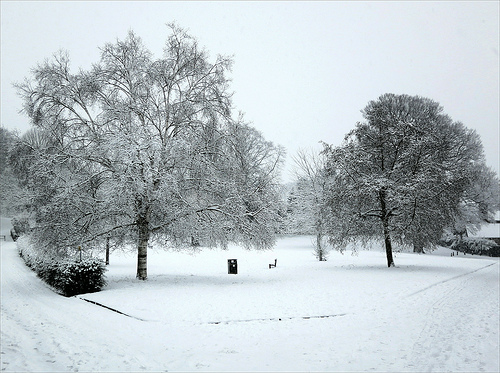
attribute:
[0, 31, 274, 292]
tree — snow-covered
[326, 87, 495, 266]
tree — snow-covered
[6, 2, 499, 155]
sky — cloudy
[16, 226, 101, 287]
bushes — snow covered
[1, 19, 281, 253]
tree — leafless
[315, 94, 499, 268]
tree — leafless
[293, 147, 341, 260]
tree — leafless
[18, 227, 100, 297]
shrub — low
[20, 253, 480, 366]
ground — snow covered